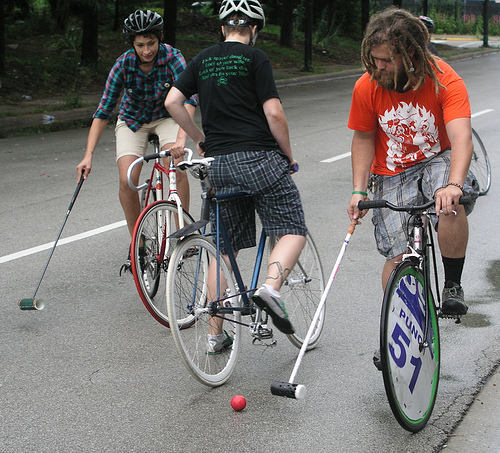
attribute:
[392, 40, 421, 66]
hair — brown, dreadlocks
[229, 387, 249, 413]
ball — red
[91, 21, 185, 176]
woman — riding